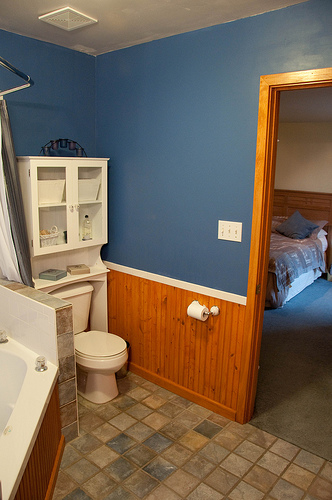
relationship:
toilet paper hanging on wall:
[185, 302, 209, 321] [96, 6, 330, 416]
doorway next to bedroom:
[236, 65, 331, 459] [247, 91, 331, 463]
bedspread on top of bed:
[266, 216, 324, 311] [264, 191, 331, 308]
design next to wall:
[39, 138, 87, 154] [1, 30, 98, 157]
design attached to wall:
[39, 138, 87, 154] [1, 30, 98, 157]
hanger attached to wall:
[0, 62, 34, 105] [1, 30, 98, 157]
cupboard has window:
[15, 155, 110, 329] [79, 169, 102, 203]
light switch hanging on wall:
[216, 218, 243, 244] [96, 6, 330, 416]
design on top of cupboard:
[39, 138, 87, 154] [15, 155, 110, 329]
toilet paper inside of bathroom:
[185, 302, 209, 321] [1, 1, 331, 498]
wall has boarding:
[96, 6, 330, 416] [109, 270, 246, 416]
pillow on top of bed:
[275, 211, 319, 240] [264, 191, 331, 308]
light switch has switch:
[216, 218, 243, 244] [234, 229, 239, 238]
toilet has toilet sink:
[52, 281, 130, 402] [50, 284, 93, 333]